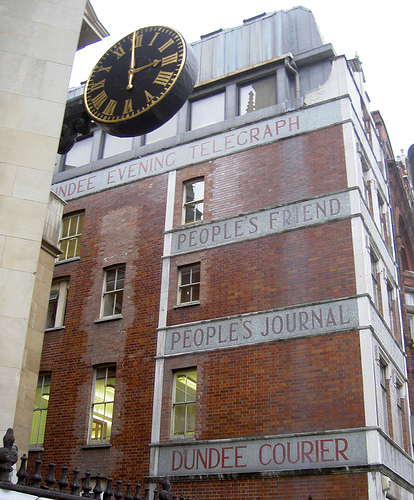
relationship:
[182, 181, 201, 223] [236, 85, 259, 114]
shows reflection. shows reflections shows reflections.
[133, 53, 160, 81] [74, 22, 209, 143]
hour hand. on clock.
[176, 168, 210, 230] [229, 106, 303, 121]
window. has pane.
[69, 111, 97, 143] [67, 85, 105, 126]
light hanging. from ceiling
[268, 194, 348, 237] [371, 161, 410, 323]
word friend. on side of building.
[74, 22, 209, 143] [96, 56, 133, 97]
round clock. has black face.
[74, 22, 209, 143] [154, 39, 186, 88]
clock. has roman numerals.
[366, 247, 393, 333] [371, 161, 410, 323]
long window. on side of building.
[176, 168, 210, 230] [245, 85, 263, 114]
window. has light.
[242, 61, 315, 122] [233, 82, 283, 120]
shiny top. has window reflection.